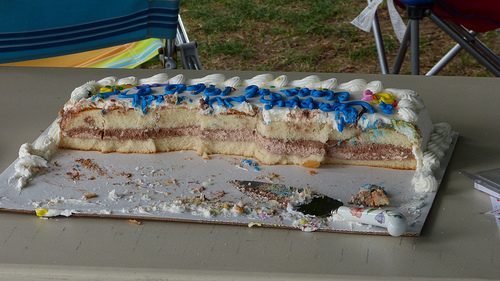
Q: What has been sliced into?
A: A cake.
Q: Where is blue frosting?
A: On the cake.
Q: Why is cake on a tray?
A: To be eaten.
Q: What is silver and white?
A: A knife.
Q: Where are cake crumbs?
A: On the tray.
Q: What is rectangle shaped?
A: The cake tray.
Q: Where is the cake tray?
A: On a table.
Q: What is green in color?
A: Grass.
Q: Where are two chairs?
A: Behind the table.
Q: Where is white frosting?
A: On cake.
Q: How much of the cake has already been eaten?
A: Over half of the cake.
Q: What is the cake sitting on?
A: A piece of cardboard.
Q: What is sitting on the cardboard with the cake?
A: A cake knife.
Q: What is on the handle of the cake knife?
A: A flower design.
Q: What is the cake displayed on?
A: A white table.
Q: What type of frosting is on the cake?
A: Buttercream.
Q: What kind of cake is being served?
A: White cake topped with white frosting.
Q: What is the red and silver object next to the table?
A: A folding chair.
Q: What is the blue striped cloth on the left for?
A: Chair back rest.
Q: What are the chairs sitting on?
A: A lawn.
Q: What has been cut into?
A: A cake.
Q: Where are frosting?
A: On the cake.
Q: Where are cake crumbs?
A: On the platter.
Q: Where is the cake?
A: On a table.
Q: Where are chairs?
A: Next to the table.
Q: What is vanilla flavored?
A: Cake.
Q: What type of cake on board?
A: Sheet.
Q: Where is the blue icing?
A: On cake.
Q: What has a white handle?
A: Knife.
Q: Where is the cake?
A: On table.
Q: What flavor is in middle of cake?
A: Chocolate.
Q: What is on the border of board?
A: White icing.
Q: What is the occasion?
A: Birthday party.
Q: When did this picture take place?
A: This picture took place in the day time.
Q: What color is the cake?
A: The cake is white,blue,and brown.